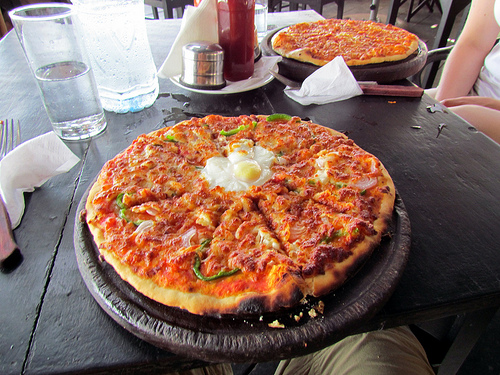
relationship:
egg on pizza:
[199, 140, 277, 192] [84, 111, 396, 317]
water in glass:
[32, 61, 102, 127] [9, 3, 107, 144]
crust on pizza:
[81, 111, 394, 317] [84, 111, 396, 317]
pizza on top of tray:
[84, 111, 396, 317] [70, 172, 412, 358]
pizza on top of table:
[84, 111, 396, 317] [0, 7, 492, 373]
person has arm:
[424, 1, 498, 146] [435, 2, 494, 103]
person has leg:
[424, 1, 498, 146] [422, 86, 481, 104]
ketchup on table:
[216, 1, 256, 84] [0, 7, 492, 373]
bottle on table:
[215, 0, 255, 83] [0, 7, 492, 373]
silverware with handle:
[270, 69, 428, 99] [352, 81, 424, 100]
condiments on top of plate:
[174, 3, 262, 93] [164, 57, 281, 97]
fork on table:
[1, 115, 21, 158] [0, 7, 492, 373]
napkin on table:
[2, 127, 75, 228] [0, 7, 492, 373]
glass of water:
[9, 3, 107, 144] [30, 57, 99, 121]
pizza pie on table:
[80, 110, 398, 317] [0, 7, 492, 373]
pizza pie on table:
[272, 18, 421, 68] [0, 7, 492, 373]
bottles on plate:
[180, 0, 254, 90] [167, 59, 276, 95]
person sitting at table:
[424, 1, 498, 146] [0, 7, 492, 373]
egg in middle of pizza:
[199, 140, 277, 192] [84, 111, 396, 317]